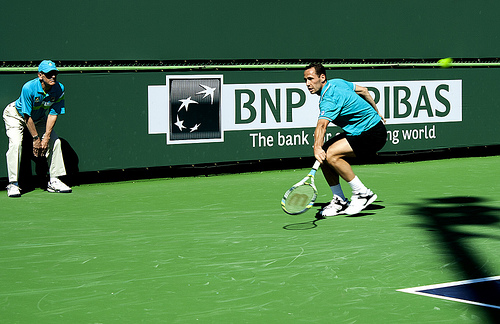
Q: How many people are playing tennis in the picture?
A: One.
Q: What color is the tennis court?
A: Green.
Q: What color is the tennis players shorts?
A: Black.